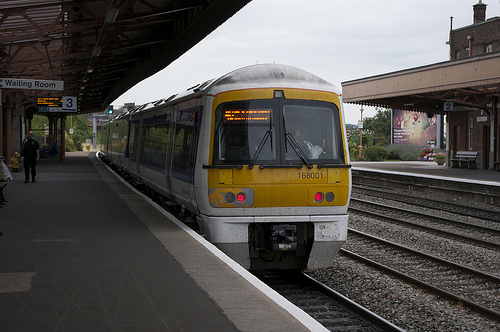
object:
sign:
[62, 97, 76, 109]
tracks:
[340, 203, 495, 332]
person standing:
[16, 130, 41, 185]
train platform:
[1, 150, 332, 330]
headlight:
[236, 193, 246, 202]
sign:
[35, 95, 62, 105]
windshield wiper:
[285, 129, 313, 169]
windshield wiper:
[251, 129, 274, 167]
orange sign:
[221, 107, 273, 123]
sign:
[0, 79, 64, 90]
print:
[298, 171, 324, 180]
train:
[90, 63, 354, 270]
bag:
[304, 142, 326, 162]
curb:
[87, 143, 334, 330]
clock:
[391, 104, 436, 154]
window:
[170, 102, 202, 184]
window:
[142, 107, 167, 172]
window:
[125, 115, 138, 158]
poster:
[391, 105, 442, 149]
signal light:
[107, 108, 115, 116]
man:
[18, 127, 42, 188]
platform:
[0, 132, 339, 322]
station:
[2, 21, 495, 332]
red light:
[313, 192, 326, 203]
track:
[282, 245, 497, 330]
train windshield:
[215, 94, 345, 167]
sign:
[442, 100, 457, 111]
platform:
[352, 158, 498, 208]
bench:
[451, 147, 482, 166]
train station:
[339, 46, 499, 181]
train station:
[0, 3, 61, 203]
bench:
[1, 175, 11, 202]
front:
[209, 78, 350, 273]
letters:
[47, 81, 57, 88]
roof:
[3, 1, 253, 112]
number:
[443, 101, 456, 111]